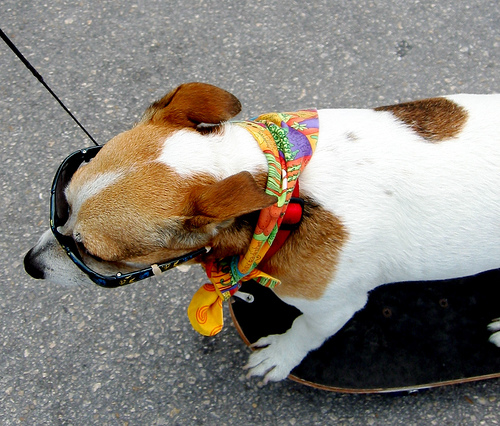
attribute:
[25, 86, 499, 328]
dog — white, brown, in sight, on the board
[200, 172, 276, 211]
ear — brown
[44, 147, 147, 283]
sunglasses — black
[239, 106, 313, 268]
bandana — colorful, black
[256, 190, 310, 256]
collar — red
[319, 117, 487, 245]
fur — white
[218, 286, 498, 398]
skateboard — black, brown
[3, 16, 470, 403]
surface — gray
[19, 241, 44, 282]
nose — black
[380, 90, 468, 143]
spots — brown, color brown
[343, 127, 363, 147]
spot — black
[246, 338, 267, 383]
nails — white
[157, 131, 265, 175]
stripe — white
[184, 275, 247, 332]
scarf — yellow